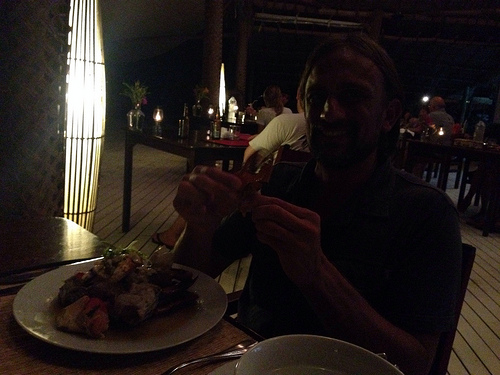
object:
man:
[170, 34, 462, 325]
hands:
[170, 169, 326, 273]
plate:
[11, 255, 230, 356]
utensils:
[160, 341, 255, 375]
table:
[0, 217, 259, 375]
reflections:
[57, 213, 97, 261]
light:
[62, 0, 105, 229]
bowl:
[234, 336, 401, 375]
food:
[55, 245, 199, 339]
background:
[107, 0, 498, 147]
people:
[416, 97, 456, 145]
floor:
[91, 140, 186, 252]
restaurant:
[0, 0, 498, 375]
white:
[35, 340, 209, 355]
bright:
[64, 61, 106, 116]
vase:
[127, 105, 145, 135]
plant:
[122, 74, 143, 118]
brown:
[0, 0, 65, 265]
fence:
[0, 0, 66, 217]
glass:
[220, 109, 229, 141]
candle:
[218, 64, 227, 117]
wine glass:
[177, 103, 191, 142]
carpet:
[427, 163, 468, 174]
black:
[481, 165, 488, 216]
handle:
[218, 338, 254, 360]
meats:
[55, 259, 201, 338]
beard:
[308, 135, 376, 169]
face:
[305, 55, 378, 159]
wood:
[122, 128, 248, 234]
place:
[209, 134, 253, 147]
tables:
[396, 124, 476, 198]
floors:
[442, 226, 498, 375]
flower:
[119, 81, 150, 111]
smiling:
[301, 85, 371, 147]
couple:
[246, 84, 294, 135]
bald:
[421, 96, 452, 110]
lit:
[155, 111, 162, 139]